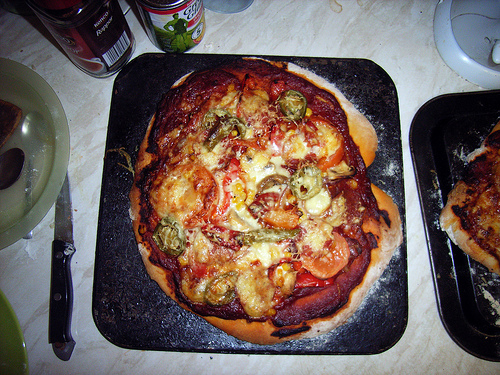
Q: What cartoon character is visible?
A: The Jolly Green Giant.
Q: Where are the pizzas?
A: On the platters.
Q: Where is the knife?
A: To the left of the pizza.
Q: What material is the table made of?
A: White marble.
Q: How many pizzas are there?
A: 2.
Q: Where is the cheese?
A: On the pizza.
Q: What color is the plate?
A: Green.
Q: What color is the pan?
A: Black.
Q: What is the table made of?
A: Marble.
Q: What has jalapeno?
A: Pizza.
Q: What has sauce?
A: Pizza.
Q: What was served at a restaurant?
A: Gourmet focaccia.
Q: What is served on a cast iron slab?
A: Focaccia.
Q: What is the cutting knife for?
A: Focaccia.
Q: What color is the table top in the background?
A: White.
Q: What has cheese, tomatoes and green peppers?
A: Focaccia.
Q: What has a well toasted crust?
A: Focaccia.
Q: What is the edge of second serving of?
A: Focaccia.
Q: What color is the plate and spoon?
A: Beige and silver.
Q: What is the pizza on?
A: A pan.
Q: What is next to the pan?
A: A knife.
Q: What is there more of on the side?
A: Pizza.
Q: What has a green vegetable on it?
A: The pizza.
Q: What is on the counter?
A: The pizza.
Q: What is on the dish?
A: A spoon.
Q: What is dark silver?
A: The pan.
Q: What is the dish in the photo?
A: Pizza.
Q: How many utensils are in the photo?
A: One.